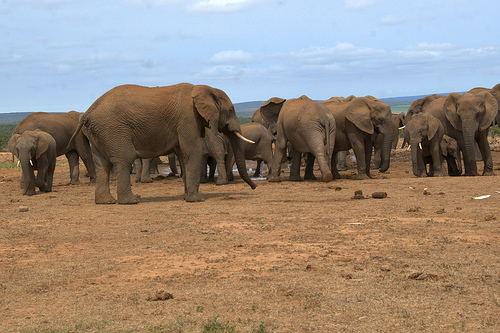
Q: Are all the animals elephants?
A: Yes, all the animals are elephants.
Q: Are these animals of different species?
A: No, all the animals are elephants.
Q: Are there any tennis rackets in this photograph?
A: No, there are no tennis rackets.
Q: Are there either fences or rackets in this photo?
A: No, there are no rackets or fences.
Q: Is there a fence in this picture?
A: No, there are no fences.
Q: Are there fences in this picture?
A: No, there are no fences.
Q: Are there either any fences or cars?
A: No, there are no fences or cars.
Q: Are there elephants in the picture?
A: Yes, there is an elephant.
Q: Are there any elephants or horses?
A: Yes, there is an elephant.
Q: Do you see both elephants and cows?
A: No, there is an elephant but no cows.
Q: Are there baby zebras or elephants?
A: Yes, there is a baby elephant.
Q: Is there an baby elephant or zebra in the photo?
A: Yes, there is a baby elephant.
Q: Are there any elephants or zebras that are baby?
A: Yes, the elephant is a baby.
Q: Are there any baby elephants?
A: Yes, there is a baby elephant.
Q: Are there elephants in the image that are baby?
A: Yes, there is an elephant that is a baby.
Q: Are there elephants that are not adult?
A: Yes, there is an baby elephant.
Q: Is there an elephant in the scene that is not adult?
A: Yes, there is an baby elephant.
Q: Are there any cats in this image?
A: No, there are no cats.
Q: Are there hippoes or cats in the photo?
A: No, there are no cats or hippoes.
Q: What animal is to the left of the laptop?
A: The animal is an elephant.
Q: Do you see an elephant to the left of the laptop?
A: Yes, there is an elephant to the left of the laptop.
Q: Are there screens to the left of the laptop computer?
A: No, there is an elephant to the left of the laptop computer.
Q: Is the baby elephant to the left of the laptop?
A: Yes, the elephant is to the left of the laptop.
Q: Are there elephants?
A: Yes, there are elephants.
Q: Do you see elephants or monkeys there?
A: Yes, there are elephants.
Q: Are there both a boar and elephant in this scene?
A: No, there are elephants but no boars.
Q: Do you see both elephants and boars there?
A: No, there are elephants but no boars.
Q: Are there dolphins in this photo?
A: No, there are no dolphins.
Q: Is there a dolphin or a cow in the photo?
A: No, there are no dolphins or cows.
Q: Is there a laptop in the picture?
A: Yes, there is a laptop.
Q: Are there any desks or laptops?
A: Yes, there is a laptop.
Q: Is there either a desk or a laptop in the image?
A: Yes, there is a laptop.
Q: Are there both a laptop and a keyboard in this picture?
A: No, there is a laptop but no keyboards.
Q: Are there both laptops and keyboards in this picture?
A: No, there is a laptop but no keyboards.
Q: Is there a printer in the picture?
A: No, there are no printers.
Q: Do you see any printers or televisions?
A: No, there are no printers or televisions.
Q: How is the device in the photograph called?
A: The device is a laptop.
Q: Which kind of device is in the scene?
A: The device is a laptop.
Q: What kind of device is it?
A: The device is a laptop.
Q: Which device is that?
A: This is a laptop.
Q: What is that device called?
A: This is a laptop.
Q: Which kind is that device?
A: This is a laptop.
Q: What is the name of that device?
A: This is a laptop.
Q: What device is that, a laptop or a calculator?
A: This is a laptop.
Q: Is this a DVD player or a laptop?
A: This is a laptop.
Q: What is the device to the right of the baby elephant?
A: The device is a laptop.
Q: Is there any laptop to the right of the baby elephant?
A: Yes, there is a laptop to the right of the elephant.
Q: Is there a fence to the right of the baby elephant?
A: No, there is a laptop to the right of the elephant.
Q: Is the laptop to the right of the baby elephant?
A: Yes, the laptop is to the right of the elephant.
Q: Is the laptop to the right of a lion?
A: No, the laptop is to the right of the elephant.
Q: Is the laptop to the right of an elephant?
A: Yes, the laptop is to the right of an elephant.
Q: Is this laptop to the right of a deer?
A: No, the laptop is to the right of an elephant.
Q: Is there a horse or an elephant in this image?
A: Yes, there is an elephant.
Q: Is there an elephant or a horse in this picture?
A: Yes, there is an elephant.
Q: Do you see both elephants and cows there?
A: No, there is an elephant but no cows.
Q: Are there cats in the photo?
A: No, there are no cats.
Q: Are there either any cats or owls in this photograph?
A: No, there are no cats or owls.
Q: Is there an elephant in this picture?
A: Yes, there is an elephant.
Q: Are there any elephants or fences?
A: Yes, there is an elephant.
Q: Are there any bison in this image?
A: No, there are no bison.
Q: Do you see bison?
A: No, there are no bison.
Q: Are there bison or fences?
A: No, there are no bison or fences.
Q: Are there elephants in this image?
A: Yes, there is an elephant.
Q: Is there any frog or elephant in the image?
A: Yes, there is an elephant.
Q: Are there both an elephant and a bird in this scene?
A: No, there is an elephant but no birds.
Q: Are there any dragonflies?
A: No, there are no dragonflies.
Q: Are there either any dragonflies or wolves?
A: No, there are no dragonflies or wolves.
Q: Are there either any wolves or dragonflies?
A: No, there are no dragonflies or wolves.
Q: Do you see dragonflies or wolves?
A: No, there are no dragonflies or wolves.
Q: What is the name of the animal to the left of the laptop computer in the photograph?
A: The animal is an elephant.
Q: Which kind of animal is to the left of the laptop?
A: The animal is an elephant.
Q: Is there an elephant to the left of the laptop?
A: Yes, there is an elephant to the left of the laptop.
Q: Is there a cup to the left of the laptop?
A: No, there is an elephant to the left of the laptop.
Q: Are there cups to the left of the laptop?
A: No, there is an elephant to the left of the laptop.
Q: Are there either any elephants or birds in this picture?
A: Yes, there is an elephant.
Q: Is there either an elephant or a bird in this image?
A: Yes, there is an elephant.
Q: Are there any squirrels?
A: No, there are no squirrels.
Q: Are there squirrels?
A: No, there are no squirrels.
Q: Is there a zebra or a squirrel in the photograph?
A: No, there are no squirrels or zebras.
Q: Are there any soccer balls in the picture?
A: No, there are no soccer balls.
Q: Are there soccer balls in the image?
A: No, there are no soccer balls.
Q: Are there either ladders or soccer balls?
A: No, there are no soccer balls or ladders.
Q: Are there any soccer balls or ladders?
A: No, there are no soccer balls or ladders.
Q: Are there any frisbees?
A: No, there are no frisbees.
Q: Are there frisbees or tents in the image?
A: No, there are no frisbees or tents.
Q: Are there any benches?
A: No, there are no benches.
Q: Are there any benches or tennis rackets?
A: No, there are no benches or tennis rackets.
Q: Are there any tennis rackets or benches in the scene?
A: No, there are no benches or tennis rackets.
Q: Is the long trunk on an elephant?
A: Yes, the trunk is on an elephant.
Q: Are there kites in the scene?
A: No, there are no kites.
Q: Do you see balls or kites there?
A: No, there are no kites or balls.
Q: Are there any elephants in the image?
A: Yes, there is an elephant.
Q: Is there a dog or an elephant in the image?
A: Yes, there is an elephant.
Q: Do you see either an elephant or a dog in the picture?
A: Yes, there is an elephant.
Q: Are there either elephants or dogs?
A: Yes, there is an elephant.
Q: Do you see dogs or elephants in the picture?
A: Yes, there is an elephant.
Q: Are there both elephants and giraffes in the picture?
A: No, there is an elephant but no giraffes.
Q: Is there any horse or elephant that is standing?
A: Yes, the elephant is standing.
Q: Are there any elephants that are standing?
A: Yes, there is an elephant that is standing.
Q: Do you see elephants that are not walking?
A: Yes, there is an elephant that is standing .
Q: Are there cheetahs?
A: No, there are no cheetahs.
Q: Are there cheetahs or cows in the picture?
A: No, there are no cheetahs or cows.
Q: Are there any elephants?
A: Yes, there are elephants.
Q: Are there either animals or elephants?
A: Yes, there are elephants.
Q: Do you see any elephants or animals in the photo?
A: Yes, there are elephants.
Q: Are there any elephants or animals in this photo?
A: Yes, there are elephants.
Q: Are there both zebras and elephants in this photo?
A: No, there are elephants but no zebras.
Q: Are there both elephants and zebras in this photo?
A: No, there are elephants but no zebras.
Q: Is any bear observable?
A: No, there are no bears.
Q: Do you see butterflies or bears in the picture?
A: No, there are no bears or butterflies.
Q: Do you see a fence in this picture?
A: No, there are no fences.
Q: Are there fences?
A: No, there are no fences.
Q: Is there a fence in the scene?
A: No, there are no fences.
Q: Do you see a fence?
A: No, there are no fences.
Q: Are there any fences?
A: No, there are no fences.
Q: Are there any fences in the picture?
A: No, there are no fences.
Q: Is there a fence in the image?
A: No, there are no fences.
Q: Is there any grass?
A: Yes, there is grass.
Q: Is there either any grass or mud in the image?
A: Yes, there is grass.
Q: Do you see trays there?
A: No, there are no trays.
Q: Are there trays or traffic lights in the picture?
A: No, there are no trays or traffic lights.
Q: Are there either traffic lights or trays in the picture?
A: No, there are no trays or traffic lights.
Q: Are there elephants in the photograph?
A: Yes, there are elephants.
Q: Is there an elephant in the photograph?
A: Yes, there are elephants.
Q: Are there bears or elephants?
A: Yes, there are elephants.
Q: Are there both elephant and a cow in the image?
A: No, there are elephants but no cows.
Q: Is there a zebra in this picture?
A: No, there are no zebras.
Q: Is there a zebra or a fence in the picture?
A: No, there are no zebras or fences.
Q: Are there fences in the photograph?
A: No, there are no fences.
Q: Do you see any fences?
A: No, there are no fences.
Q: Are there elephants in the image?
A: Yes, there is an elephant.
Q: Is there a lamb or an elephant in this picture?
A: Yes, there is an elephant.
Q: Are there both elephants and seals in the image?
A: No, there is an elephant but no seals.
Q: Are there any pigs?
A: No, there are no pigs.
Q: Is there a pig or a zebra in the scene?
A: No, there are no pigs or zebras.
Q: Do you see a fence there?
A: No, there are no fences.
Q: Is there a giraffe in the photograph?
A: No, there are no giraffes.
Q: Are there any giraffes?
A: No, there are no giraffes.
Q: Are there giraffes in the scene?
A: No, there are no giraffes.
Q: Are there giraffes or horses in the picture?
A: No, there are no giraffes or horses.